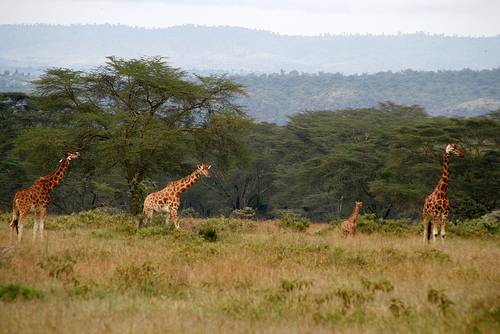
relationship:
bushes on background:
[70, 198, 499, 234] [8, 156, 482, 232]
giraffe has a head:
[16, 154, 65, 230] [56, 148, 81, 166]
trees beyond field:
[2, 52, 484, 216] [1, 204, 481, 329]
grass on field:
[195, 255, 265, 301] [225, 244, 496, 325]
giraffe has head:
[137, 161, 212, 230] [195, 161, 213, 180]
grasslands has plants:
[148, 227, 449, 307] [386, 242, 447, 265]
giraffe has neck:
[141, 155, 213, 227] [178, 164, 200, 189]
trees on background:
[0, 52, 278, 214] [1, 22, 499, 129]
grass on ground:
[0, 207, 499, 333] [6, 211, 496, 332]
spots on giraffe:
[157, 189, 167, 203] [135, 160, 213, 229]